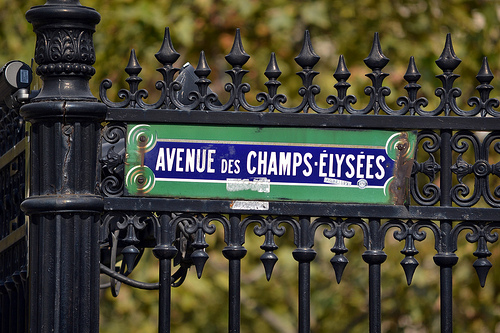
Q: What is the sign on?
A: Fence.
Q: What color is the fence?
A: Black.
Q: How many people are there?
A: Zero.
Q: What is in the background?
A: Trees.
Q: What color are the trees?
A: Green.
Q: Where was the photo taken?
A: France.